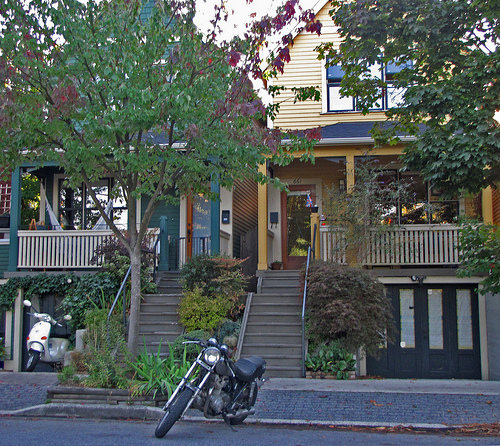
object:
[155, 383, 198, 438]
tire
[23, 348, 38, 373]
tire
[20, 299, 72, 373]
moped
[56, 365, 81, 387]
weeds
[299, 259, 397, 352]
bush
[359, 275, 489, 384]
garage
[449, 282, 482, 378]
doors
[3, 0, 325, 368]
tree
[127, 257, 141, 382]
trunk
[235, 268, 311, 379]
staircase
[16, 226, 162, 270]
railing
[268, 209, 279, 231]
mailbox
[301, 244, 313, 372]
railing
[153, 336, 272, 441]
motorcycle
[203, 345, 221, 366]
headlight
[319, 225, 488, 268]
rail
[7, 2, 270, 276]
house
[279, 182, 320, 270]
door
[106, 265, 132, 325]
rail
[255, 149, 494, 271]
porch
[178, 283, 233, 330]
bush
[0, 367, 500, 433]
sidewalk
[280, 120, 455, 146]
roof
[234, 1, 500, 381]
home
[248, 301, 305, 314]
stair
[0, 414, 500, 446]
road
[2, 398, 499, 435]
edge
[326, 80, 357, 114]
window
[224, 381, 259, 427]
wheels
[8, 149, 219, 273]
porch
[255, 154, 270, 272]
post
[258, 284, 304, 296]
steps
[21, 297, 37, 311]
mirrors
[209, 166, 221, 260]
post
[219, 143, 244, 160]
leaves